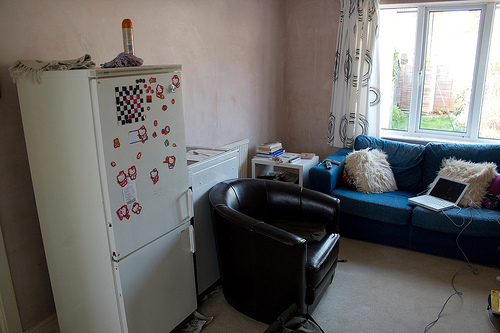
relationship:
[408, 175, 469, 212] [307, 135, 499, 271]
laptop on couch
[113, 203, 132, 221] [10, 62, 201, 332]
magnet on refrigerator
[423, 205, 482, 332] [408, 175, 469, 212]
cord for laptop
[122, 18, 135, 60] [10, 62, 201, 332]
aeresol can on refrigerator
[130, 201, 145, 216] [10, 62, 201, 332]
magnet on refrigerator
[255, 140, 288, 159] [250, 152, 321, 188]
books on table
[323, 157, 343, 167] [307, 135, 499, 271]
remote on couch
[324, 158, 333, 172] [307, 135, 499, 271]
remote on couch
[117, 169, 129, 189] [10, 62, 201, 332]
magnet on refrigerator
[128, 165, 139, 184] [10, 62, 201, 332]
magnet on refrigerator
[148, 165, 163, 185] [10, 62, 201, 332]
magnet on refrigerator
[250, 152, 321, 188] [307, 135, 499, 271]
table beside couch